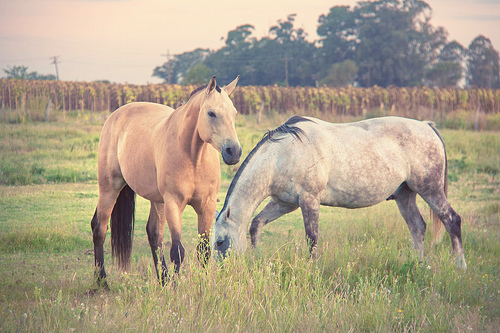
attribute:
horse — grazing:
[74, 69, 256, 298]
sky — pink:
[1, 3, 219, 41]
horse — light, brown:
[88, 72, 243, 294]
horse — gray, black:
[217, 103, 469, 288]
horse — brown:
[90, 82, 242, 278]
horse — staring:
[85, 89, 238, 255]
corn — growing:
[9, 78, 479, 125]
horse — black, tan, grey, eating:
[212, 114, 469, 268]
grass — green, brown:
[21, 186, 51, 239]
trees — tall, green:
[317, 23, 416, 79]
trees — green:
[132, 15, 499, 149]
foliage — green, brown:
[0, 80, 499, 127]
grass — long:
[348, 240, 439, 295]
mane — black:
[218, 118, 307, 161]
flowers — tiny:
[196, 220, 218, 253]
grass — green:
[6, 96, 498, 328]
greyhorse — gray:
[214, 109, 467, 279]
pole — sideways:
[46, 48, 67, 84]